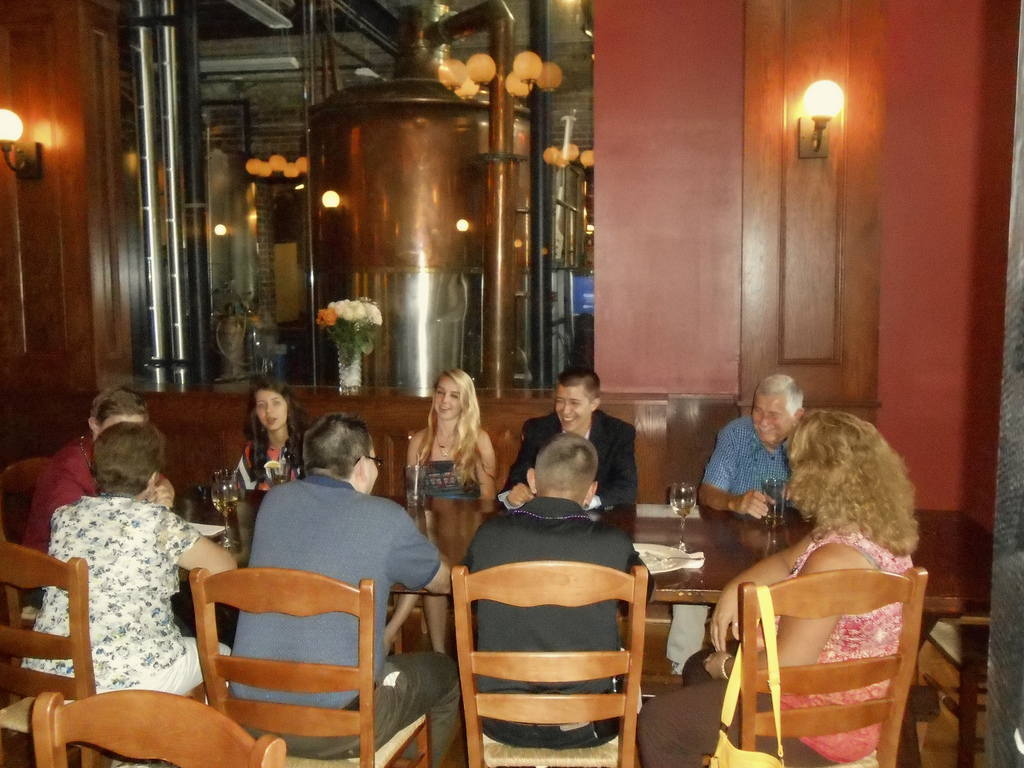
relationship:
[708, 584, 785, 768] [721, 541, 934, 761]
bag hanging off chair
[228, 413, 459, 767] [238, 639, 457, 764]
family wearing pants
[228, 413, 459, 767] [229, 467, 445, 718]
family wearing shirt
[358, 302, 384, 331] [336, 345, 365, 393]
flower in vase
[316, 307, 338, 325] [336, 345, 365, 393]
flower in vase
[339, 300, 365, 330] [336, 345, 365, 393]
flower in vase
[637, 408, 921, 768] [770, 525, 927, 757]
family wearing top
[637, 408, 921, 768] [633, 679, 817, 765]
family wearing pants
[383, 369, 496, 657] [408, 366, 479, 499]
girl with hair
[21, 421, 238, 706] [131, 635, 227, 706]
woman wearing pants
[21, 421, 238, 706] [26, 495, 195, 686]
woman wearing shirt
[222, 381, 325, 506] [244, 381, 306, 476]
woman with hair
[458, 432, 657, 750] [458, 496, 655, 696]
family wearing jacket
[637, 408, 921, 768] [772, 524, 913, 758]
family wearing top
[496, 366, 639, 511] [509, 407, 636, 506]
family wearing jacket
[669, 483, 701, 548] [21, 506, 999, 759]
glass on top of table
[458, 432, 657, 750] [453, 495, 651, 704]
family wearing jacket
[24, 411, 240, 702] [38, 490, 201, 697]
woman wearing shirt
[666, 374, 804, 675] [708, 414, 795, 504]
family wearing shirt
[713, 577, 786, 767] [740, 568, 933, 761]
bag hanging on chair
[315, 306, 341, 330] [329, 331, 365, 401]
flower in vase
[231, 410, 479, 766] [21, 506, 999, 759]
family sitting around table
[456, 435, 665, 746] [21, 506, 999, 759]
family sitting around table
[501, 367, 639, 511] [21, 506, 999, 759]
family sitting around table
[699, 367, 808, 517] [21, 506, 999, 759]
family sitting around table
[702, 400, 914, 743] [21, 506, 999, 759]
family sitting around table